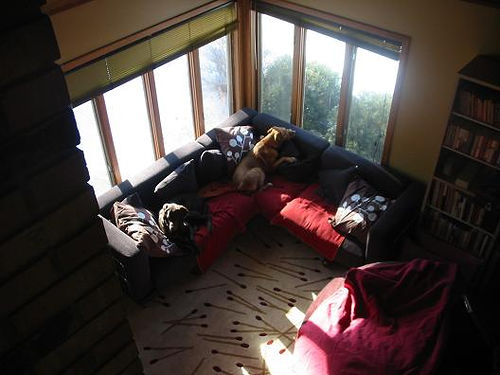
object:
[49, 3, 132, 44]
wall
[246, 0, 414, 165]
blinds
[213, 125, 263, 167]
pillow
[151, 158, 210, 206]
pillow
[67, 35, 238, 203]
blinds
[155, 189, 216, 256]
dog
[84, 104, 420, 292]
couch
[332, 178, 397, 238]
pillow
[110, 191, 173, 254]
pillow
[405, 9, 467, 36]
wall